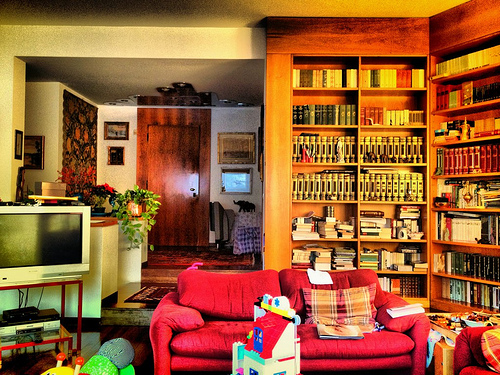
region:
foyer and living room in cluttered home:
[4, 5, 494, 370]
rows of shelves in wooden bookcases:
[265, 0, 496, 320]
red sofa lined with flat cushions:
[147, 262, 427, 367]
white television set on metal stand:
[2, 205, 87, 370]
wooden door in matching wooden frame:
[131, 105, 211, 255]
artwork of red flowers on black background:
[55, 85, 95, 185]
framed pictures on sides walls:
[95, 101, 256, 198]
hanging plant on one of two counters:
[90, 185, 160, 316]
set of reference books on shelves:
[290, 130, 422, 200]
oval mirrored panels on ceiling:
[36, 55, 261, 107]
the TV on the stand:
[0, 203, 91, 281]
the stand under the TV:
[1, 280, 83, 359]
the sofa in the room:
[148, 267, 432, 374]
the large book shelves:
[290, 30, 498, 317]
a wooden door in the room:
[141, 120, 201, 246]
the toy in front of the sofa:
[231, 293, 301, 373]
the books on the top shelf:
[290, 63, 426, 88]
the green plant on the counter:
[113, 184, 158, 251]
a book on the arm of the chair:
[386, 303, 426, 320]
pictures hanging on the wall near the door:
[216, 129, 254, 195]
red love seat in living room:
[158, 269, 420, 374]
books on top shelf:
[288, 66, 426, 92]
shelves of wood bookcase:
[287, 54, 430, 267]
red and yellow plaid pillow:
[303, 281, 381, 326]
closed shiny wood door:
[142, 125, 204, 249]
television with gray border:
[6, 204, 91, 274]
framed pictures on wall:
[102, 120, 128, 167]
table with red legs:
[0, 279, 84, 358]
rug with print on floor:
[147, 241, 255, 268]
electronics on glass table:
[0, 307, 60, 345]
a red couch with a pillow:
[147, 275, 424, 373]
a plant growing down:
[110, 185, 158, 250]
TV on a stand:
[0, 207, 90, 361]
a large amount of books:
[290, 53, 495, 309]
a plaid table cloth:
[237, 211, 260, 258]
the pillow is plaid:
[292, 283, 384, 329]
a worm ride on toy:
[37, 330, 143, 372]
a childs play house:
[222, 295, 302, 372]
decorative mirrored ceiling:
[103, 78, 249, 109]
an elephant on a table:
[231, 195, 260, 214]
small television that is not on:
[2, 209, 92, 283]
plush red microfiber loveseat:
[151, 263, 436, 373]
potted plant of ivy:
[111, 188, 160, 249]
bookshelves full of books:
[295, 95, 429, 270]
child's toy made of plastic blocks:
[229, 294, 296, 374]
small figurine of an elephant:
[233, 193, 260, 213]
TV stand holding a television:
[0, 203, 95, 365]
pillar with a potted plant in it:
[114, 188, 154, 316]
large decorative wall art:
[59, 95, 98, 188]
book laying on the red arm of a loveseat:
[381, 294, 428, 333]